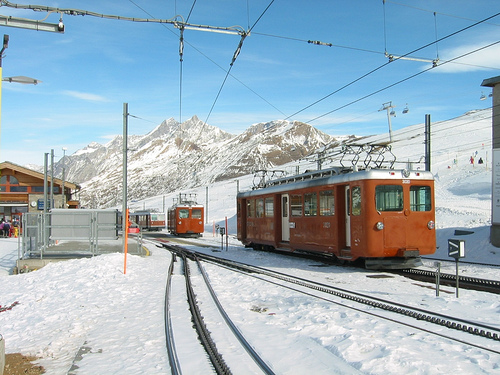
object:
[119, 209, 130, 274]
pole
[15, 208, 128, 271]
enclosure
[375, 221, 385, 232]
lights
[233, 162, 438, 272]
train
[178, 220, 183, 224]
lights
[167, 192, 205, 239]
train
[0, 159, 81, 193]
roof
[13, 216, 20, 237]
people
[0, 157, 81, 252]
station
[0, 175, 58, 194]
windows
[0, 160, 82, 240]
building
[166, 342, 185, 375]
edge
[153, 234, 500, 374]
rail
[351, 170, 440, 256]
front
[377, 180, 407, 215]
window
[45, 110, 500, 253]
mountain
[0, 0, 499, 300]
background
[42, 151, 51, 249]
poles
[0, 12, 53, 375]
side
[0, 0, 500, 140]
wires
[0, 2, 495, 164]
sky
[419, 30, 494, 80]
clouds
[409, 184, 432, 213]
windshield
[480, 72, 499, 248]
tower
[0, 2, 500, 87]
ski lift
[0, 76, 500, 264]
distance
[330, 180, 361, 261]
entrance